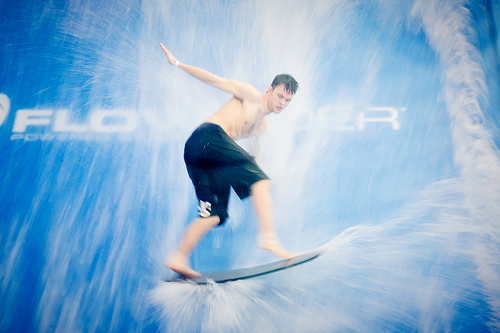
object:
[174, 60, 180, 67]
wristband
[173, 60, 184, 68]
wrist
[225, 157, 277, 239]
leg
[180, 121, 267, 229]
shorts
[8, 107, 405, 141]
sign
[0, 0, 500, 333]
wall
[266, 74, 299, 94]
dark hair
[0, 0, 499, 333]
splashing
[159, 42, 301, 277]
boy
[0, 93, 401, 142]
advertisement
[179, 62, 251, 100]
arm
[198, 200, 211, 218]
design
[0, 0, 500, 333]
water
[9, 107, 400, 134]
lettering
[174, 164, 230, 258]
left leg